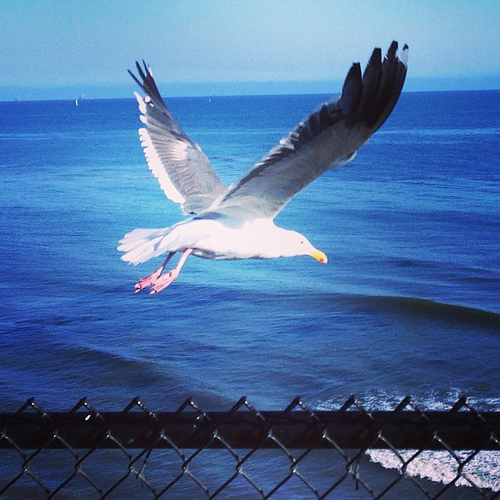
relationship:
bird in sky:
[117, 39, 410, 296] [11, 11, 393, 315]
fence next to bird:
[6, 401, 484, 497] [117, 39, 410, 296]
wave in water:
[360, 288, 497, 318] [0, 88, 497, 495]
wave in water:
[382, 198, 485, 223] [0, 88, 497, 495]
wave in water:
[420, 252, 493, 281] [0, 88, 497, 495]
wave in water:
[56, 340, 148, 380] [0, 88, 497, 495]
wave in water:
[417, 125, 470, 141] [0, 88, 497, 495]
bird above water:
[117, 39, 410, 296] [3, 0, 498, 499]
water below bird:
[0, 88, 497, 495] [117, 39, 410, 296]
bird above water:
[117, 39, 410, 296] [22, 280, 368, 393]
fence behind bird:
[6, 401, 484, 497] [110, 31, 422, 303]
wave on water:
[72, 331, 206, 404] [0, 88, 497, 495]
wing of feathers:
[125, 55, 225, 215] [213, 38, 410, 220]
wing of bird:
[125, 55, 225, 215] [117, 39, 410, 296]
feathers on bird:
[91, 53, 421, 206] [48, 28, 450, 348]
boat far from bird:
[73, 97, 79, 107] [117, 39, 410, 296]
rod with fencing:
[0, 409, 182, 444] [173, 420, 429, 496]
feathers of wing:
[213, 38, 410, 220] [125, 55, 222, 215]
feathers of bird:
[213, 38, 410, 220] [117, 39, 410, 296]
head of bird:
[281, 224, 332, 271] [110, 31, 422, 303]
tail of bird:
[118, 220, 169, 267] [96, 35, 466, 272]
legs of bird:
[133, 247, 192, 292] [117, 39, 410, 296]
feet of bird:
[128, 249, 188, 304] [117, 39, 410, 296]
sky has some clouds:
[2, 2, 487, 181] [162, 22, 304, 70]